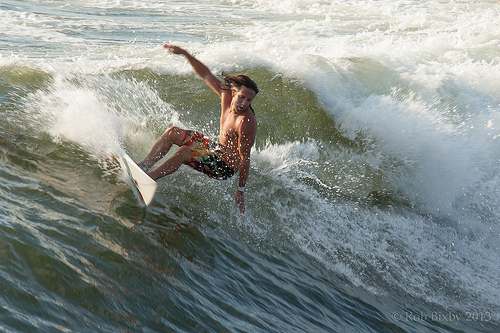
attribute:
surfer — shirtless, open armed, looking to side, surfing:
[134, 41, 259, 213]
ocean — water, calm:
[1, 1, 498, 331]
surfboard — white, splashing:
[121, 148, 158, 204]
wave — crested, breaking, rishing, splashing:
[0, 41, 497, 331]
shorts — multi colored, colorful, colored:
[178, 128, 237, 182]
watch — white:
[236, 183, 249, 194]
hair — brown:
[218, 68, 260, 95]